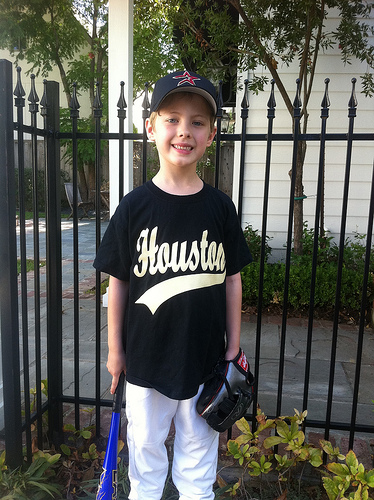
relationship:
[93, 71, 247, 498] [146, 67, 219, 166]
boy has head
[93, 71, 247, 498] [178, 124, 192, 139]
boy has nose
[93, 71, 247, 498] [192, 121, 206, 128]
boy has eye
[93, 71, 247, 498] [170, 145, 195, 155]
boy has mouth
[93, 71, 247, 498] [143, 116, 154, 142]
boy has ear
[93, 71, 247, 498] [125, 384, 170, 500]
boy has leg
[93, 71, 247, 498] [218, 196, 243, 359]
boy has arm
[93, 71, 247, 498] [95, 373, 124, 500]
boy holding baseball bat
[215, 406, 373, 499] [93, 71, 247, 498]
plant next to boy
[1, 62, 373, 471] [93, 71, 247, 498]
fence behind boy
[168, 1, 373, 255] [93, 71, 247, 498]
tree behind boy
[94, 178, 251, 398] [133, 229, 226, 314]
shirt has name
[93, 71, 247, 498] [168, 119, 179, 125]
boy has eye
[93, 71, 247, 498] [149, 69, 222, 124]
boy wearing cap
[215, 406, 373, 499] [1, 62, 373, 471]
plant in front of fence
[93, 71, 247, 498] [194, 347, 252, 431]
boy wearing baseball glove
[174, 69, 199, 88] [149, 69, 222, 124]
star in front of cap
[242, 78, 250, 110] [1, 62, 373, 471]
point on top of fence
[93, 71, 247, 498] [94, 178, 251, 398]
boy wearing shirt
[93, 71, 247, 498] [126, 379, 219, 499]
boy wearing pants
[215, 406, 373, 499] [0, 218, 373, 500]
plant on top of ground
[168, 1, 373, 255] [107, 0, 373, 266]
tree near house